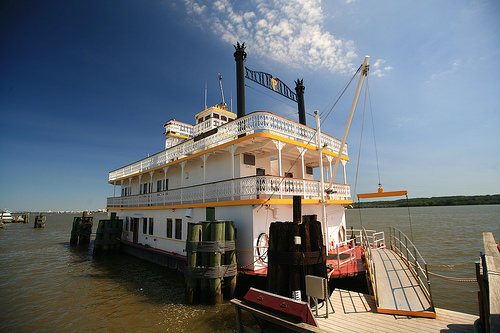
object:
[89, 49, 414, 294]
boat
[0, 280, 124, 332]
water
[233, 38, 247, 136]
post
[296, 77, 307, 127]
post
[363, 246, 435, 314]
entrance ramp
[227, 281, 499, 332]
dock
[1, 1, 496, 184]
sky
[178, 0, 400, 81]
clouds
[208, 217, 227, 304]
poles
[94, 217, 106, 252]
poles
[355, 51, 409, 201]
pulley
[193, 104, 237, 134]
pilot house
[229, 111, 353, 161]
balcony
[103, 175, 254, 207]
balcony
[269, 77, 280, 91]
letter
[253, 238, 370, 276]
deck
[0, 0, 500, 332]
photo